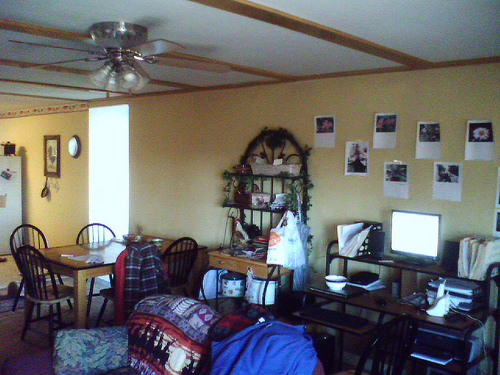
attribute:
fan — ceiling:
[5, 7, 237, 107]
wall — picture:
[140, 102, 198, 207]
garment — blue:
[208, 320, 319, 371]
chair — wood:
[11, 245, 73, 344]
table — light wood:
[54, 220, 192, 275]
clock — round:
[65, 131, 83, 162]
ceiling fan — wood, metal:
[7, 5, 238, 122]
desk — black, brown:
[283, 217, 498, 354]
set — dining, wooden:
[10, 224, 217, 347]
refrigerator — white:
[3, 157, 28, 264]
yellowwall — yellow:
[0, 80, 499, 327]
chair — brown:
[14, 244, 76, 340]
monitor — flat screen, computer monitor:
[387, 206, 445, 266]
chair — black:
[23, 239, 70, 336]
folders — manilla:
[430, 233, 497, 270]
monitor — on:
[384, 207, 445, 262]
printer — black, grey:
[398, 317, 488, 366]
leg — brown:
[71, 269, 108, 336]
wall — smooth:
[131, 96, 211, 241]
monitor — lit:
[379, 201, 445, 263]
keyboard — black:
[294, 304, 370, 331]